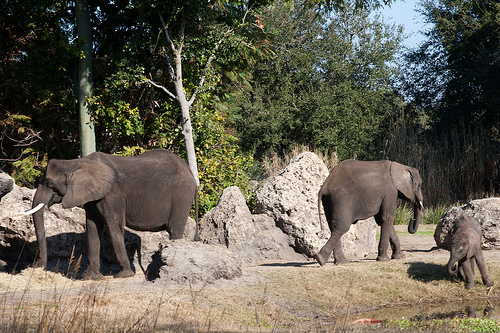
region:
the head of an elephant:
[38, 150, 83, 207]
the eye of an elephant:
[43, 176, 55, 187]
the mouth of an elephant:
[45, 187, 60, 207]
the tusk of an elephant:
[15, 200, 45, 220]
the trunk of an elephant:
[23, 187, 53, 275]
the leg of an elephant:
[98, 207, 133, 268]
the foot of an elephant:
[108, 262, 138, 279]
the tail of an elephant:
[190, 183, 207, 244]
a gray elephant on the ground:
[301, 150, 431, 266]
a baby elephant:
[436, 207, 496, 289]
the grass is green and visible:
[156, 40, 326, 161]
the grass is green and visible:
[186, 44, 386, 253]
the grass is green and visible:
[194, 82, 268, 177]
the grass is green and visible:
[171, 61, 244, 158]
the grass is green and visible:
[133, 41, 272, 198]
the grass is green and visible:
[194, 65, 325, 222]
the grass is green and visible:
[155, 28, 308, 258]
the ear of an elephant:
[54, 152, 118, 212]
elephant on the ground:
[311, 138, 427, 244]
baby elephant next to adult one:
[441, 206, 486, 296]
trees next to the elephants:
[127, 12, 347, 102]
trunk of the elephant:
[0, 191, 57, 261]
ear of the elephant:
[60, 152, 120, 202]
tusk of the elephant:
[10, 191, 50, 221]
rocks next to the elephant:
[216, 185, 296, 246]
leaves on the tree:
[305, 50, 365, 101]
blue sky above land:
[381, 5, 431, 45]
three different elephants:
[35, 72, 495, 282]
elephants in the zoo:
[16, 145, 498, 328]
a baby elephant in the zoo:
[435, 212, 497, 293]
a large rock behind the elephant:
[192, 145, 366, 292]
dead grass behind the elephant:
[367, 111, 491, 207]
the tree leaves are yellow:
[102, 75, 259, 228]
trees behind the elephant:
[2, 0, 394, 172]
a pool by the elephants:
[302, 276, 489, 328]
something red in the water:
[334, 310, 404, 329]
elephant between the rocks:
[0, 126, 232, 282]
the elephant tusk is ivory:
[12, 195, 64, 226]